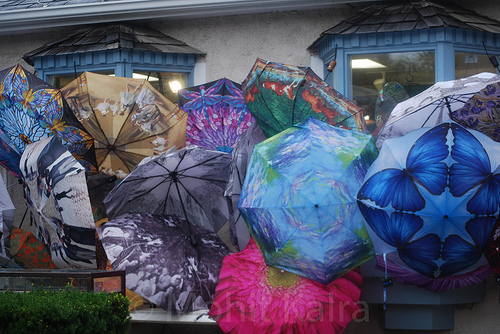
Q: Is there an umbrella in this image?
A: Yes, there is an umbrella.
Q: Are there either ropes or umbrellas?
A: Yes, there is an umbrella.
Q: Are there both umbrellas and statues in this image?
A: No, there is an umbrella but no statues.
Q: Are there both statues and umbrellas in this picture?
A: No, there is an umbrella but no statues.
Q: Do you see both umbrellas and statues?
A: No, there is an umbrella but no statues.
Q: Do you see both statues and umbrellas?
A: No, there is an umbrella but no statues.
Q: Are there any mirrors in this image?
A: No, there are no mirrors.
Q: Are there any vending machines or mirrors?
A: No, there are no mirrors or vending machines.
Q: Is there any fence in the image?
A: No, there are no fences.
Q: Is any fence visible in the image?
A: No, there are no fences.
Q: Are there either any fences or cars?
A: No, there are no fences or cars.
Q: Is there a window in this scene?
A: Yes, there is a window.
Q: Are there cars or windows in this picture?
A: Yes, there is a window.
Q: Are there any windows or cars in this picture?
A: Yes, there is a window.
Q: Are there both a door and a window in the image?
A: No, there is a window but no doors.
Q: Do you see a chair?
A: No, there are no chairs.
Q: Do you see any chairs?
A: No, there are no chairs.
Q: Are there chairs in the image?
A: No, there are no chairs.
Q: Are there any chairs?
A: No, there are no chairs.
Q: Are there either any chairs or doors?
A: No, there are no chairs or doors.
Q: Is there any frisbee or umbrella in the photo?
A: Yes, there is an umbrella.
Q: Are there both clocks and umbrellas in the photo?
A: No, there is an umbrella but no clocks.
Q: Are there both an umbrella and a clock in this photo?
A: No, there is an umbrella but no clocks.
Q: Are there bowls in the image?
A: No, there are no bowls.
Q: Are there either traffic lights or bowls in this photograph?
A: No, there are no bowls or traffic lights.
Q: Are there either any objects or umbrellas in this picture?
A: Yes, there is an umbrella.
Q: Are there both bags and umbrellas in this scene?
A: No, there is an umbrella but no bags.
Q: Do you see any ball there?
A: No, there are no balls.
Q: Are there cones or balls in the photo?
A: No, there are no balls or cones.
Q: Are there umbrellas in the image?
A: Yes, there is an umbrella.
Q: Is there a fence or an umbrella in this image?
A: Yes, there is an umbrella.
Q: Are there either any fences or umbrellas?
A: Yes, there is an umbrella.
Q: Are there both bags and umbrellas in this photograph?
A: No, there is an umbrella but no bags.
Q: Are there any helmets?
A: No, there are no helmets.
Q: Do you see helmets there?
A: No, there are no helmets.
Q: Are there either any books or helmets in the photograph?
A: No, there are no helmets or books.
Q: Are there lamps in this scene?
A: No, there are no lamps.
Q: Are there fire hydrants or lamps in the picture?
A: No, there are no lamps or fire hydrants.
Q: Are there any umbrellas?
A: Yes, there is an umbrella.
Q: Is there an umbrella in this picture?
A: Yes, there is an umbrella.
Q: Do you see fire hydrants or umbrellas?
A: Yes, there is an umbrella.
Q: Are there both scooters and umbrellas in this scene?
A: No, there is an umbrella but no scooters.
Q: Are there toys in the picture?
A: No, there are no toys.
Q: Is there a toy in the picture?
A: No, there are no toys.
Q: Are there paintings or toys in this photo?
A: No, there are no toys or paintings.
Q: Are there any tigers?
A: No, there are no tigers.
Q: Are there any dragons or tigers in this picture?
A: No, there are no tigers or dragons.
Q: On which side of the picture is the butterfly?
A: The butterfly is on the right of the image.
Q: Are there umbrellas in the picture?
A: Yes, there is an umbrella.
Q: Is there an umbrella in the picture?
A: Yes, there is an umbrella.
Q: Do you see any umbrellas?
A: Yes, there is an umbrella.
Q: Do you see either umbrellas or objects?
A: Yes, there is an umbrella.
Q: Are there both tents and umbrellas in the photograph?
A: No, there is an umbrella but no tents.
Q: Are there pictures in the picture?
A: No, there are no pictures.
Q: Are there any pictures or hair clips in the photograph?
A: No, there are no pictures or hair clips.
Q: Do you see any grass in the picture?
A: Yes, there is grass.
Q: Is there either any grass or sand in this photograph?
A: Yes, there is grass.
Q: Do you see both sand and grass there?
A: No, there is grass but no sand.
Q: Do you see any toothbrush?
A: No, there are no toothbrushes.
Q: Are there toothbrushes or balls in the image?
A: No, there are no toothbrushes or balls.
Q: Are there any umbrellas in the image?
A: Yes, there is an umbrella.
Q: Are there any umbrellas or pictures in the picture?
A: Yes, there is an umbrella.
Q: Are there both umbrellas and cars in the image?
A: No, there is an umbrella but no cars.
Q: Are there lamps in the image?
A: No, there are no lamps.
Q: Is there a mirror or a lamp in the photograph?
A: No, there are no lamps or mirrors.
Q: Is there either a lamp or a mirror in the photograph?
A: No, there are no lamps or mirrors.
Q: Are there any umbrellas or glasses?
A: Yes, there is an umbrella.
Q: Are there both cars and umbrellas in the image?
A: No, there is an umbrella but no cars.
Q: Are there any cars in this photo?
A: No, there are no cars.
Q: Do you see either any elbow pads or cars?
A: No, there are no cars or elbow pads.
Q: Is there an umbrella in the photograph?
A: Yes, there is an umbrella.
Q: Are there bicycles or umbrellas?
A: Yes, there is an umbrella.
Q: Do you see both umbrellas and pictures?
A: No, there is an umbrella but no pictures.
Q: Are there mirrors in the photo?
A: No, there are no mirrors.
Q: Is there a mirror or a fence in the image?
A: No, there are no mirrors or fences.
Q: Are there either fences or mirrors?
A: No, there are no mirrors or fences.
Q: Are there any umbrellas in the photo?
A: Yes, there is an umbrella.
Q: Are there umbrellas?
A: Yes, there is an umbrella.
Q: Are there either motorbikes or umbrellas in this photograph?
A: Yes, there is an umbrella.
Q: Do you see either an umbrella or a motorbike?
A: Yes, there is an umbrella.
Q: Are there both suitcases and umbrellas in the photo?
A: No, there is an umbrella but no suitcases.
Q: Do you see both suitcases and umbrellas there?
A: No, there is an umbrella but no suitcases.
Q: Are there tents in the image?
A: No, there are no tents.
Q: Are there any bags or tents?
A: No, there are no tents or bags.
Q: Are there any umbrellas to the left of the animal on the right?
A: Yes, there is an umbrella to the left of the butterfly.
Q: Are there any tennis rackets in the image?
A: No, there are no tennis rackets.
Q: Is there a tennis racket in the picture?
A: No, there are no rackets.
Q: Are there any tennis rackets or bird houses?
A: No, there are no tennis rackets or bird houses.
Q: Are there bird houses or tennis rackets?
A: No, there are no tennis rackets or bird houses.